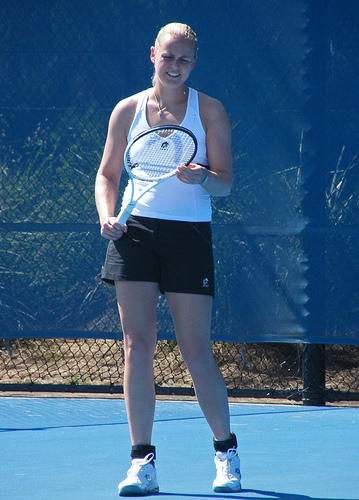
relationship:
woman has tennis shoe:
[93, 23, 242, 498] [120, 454, 160, 495]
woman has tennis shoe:
[93, 23, 242, 498] [212, 447, 241, 492]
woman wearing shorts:
[93, 23, 242, 498] [100, 213, 215, 297]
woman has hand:
[93, 23, 242, 498] [101, 219, 128, 240]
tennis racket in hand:
[117, 124, 199, 225] [101, 219, 128, 240]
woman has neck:
[93, 23, 242, 498] [153, 76, 184, 104]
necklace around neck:
[152, 86, 186, 118] [153, 76, 184, 104]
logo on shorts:
[201, 277, 211, 287] [100, 213, 215, 297]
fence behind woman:
[1, 1, 359, 407] [93, 23, 242, 498]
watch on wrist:
[200, 169, 211, 187] [200, 166, 210, 191]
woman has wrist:
[93, 23, 242, 498] [200, 166, 210, 191]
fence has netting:
[1, 1, 359, 407] [1, 1, 357, 348]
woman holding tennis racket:
[93, 23, 242, 498] [117, 124, 199, 225]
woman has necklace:
[93, 23, 242, 498] [152, 86, 186, 118]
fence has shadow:
[1, 1, 359, 407] [0, 396, 347, 432]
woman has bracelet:
[93, 23, 242, 498] [200, 169, 211, 187]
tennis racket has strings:
[117, 124, 199, 225] [126, 129, 197, 180]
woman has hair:
[93, 23, 242, 498] [152, 22, 199, 88]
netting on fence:
[1, 1, 357, 348] [1, 1, 359, 407]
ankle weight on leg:
[130, 444, 157, 460] [114, 279, 159, 458]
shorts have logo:
[100, 213, 215, 297] [201, 277, 211, 287]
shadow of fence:
[0, 396, 347, 432] [1, 1, 359, 407]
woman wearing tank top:
[93, 23, 242, 498] [121, 85, 213, 223]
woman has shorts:
[93, 23, 242, 498] [100, 213, 215, 297]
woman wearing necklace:
[93, 23, 242, 498] [152, 86, 186, 118]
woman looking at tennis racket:
[93, 23, 242, 498] [117, 124, 199, 225]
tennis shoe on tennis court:
[120, 454, 160, 495] [0, 396, 358, 498]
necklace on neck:
[152, 86, 186, 118] [153, 76, 184, 104]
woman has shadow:
[93, 23, 242, 498] [153, 490, 321, 499]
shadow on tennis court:
[153, 490, 321, 499] [0, 396, 358, 498]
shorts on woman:
[100, 213, 215, 297] [93, 23, 242, 498]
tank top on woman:
[121, 85, 213, 223] [93, 23, 242, 498]